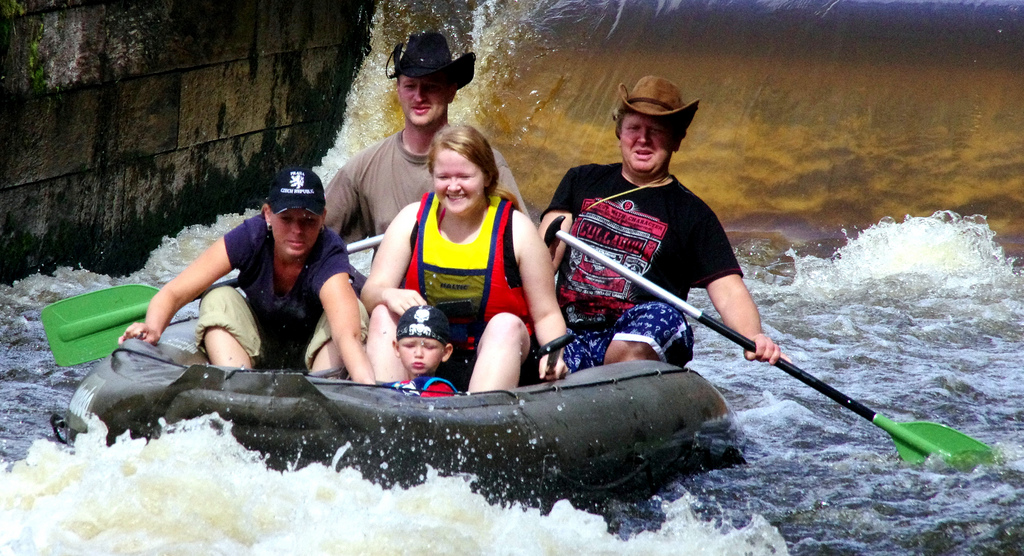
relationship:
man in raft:
[545, 82, 773, 372] [50, 331, 734, 505]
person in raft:
[353, 128, 570, 388] [50, 331, 734, 505]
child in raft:
[395, 306, 462, 402] [50, 331, 734, 505]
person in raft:
[137, 163, 369, 386] [50, 331, 734, 505]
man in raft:
[323, 43, 512, 238] [50, 331, 734, 505]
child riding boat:
[395, 306, 462, 402] [45, 334, 738, 503]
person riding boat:
[353, 128, 570, 388] [45, 334, 738, 503]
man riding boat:
[545, 82, 773, 372] [45, 334, 738, 503]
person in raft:
[137, 163, 369, 386] [69, 338, 741, 488]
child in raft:
[395, 306, 462, 402] [69, 338, 741, 488]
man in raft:
[323, 43, 512, 238] [69, 338, 741, 488]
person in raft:
[353, 128, 570, 388] [69, 338, 741, 488]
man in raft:
[545, 82, 773, 372] [69, 338, 741, 488]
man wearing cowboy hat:
[323, 43, 512, 238] [366, 24, 483, 105]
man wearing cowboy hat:
[545, 82, 774, 372] [602, 70, 704, 135]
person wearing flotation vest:
[353, 128, 570, 388] [403, 175, 546, 320]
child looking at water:
[395, 306, 462, 402] [9, 387, 915, 552]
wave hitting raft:
[13, 430, 587, 552] [69, 338, 741, 488]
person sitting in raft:
[353, 128, 570, 388] [47, 350, 750, 488]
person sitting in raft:
[137, 163, 369, 386] [47, 350, 750, 488]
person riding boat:
[137, 163, 369, 386] [45, 334, 738, 503]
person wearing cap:
[137, 163, 369, 386] [272, 164, 327, 210]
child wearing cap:
[395, 306, 454, 389] [400, 306, 453, 345]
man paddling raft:
[545, 82, 774, 372] [47, 350, 750, 488]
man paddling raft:
[323, 43, 512, 238] [47, 350, 750, 488]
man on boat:
[323, 43, 512, 238] [45, 334, 738, 503]